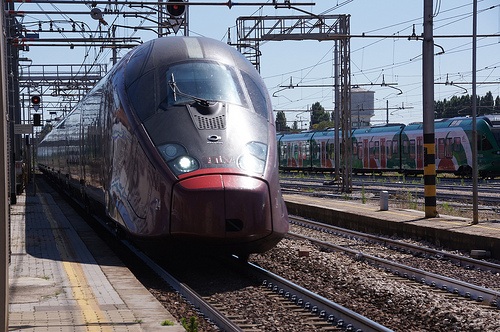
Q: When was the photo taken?
A: Daytime.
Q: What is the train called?
A: Speedtrain.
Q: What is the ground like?
A: Stony.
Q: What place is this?
A: Train station.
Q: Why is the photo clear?
A: Its during the day.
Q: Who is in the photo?
A: Nobody.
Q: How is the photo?
A: Clear.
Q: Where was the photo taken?
A: At a train station.